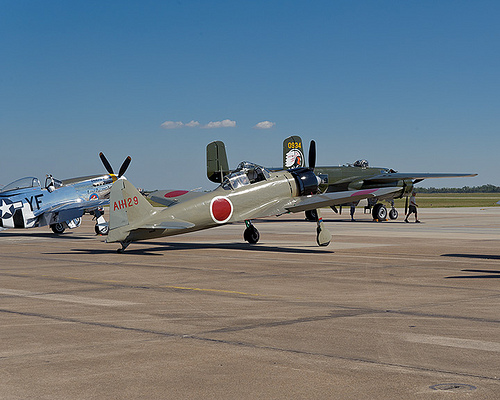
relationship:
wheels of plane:
[369, 182, 436, 222] [286, 129, 448, 214]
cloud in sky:
[154, 117, 199, 134] [3, 2, 498, 169]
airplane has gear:
[104, 134, 403, 254] [315, 220, 332, 247]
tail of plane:
[275, 129, 317, 172] [167, 143, 383, 243]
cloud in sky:
[255, 116, 274, 133] [2, 2, 497, 189]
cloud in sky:
[206, 118, 237, 128] [2, 2, 497, 189]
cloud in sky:
[154, 117, 199, 134] [2, 2, 497, 189]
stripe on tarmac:
[1, 269, 248, 294] [0, 202, 497, 398]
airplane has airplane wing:
[84, 128, 484, 255] [366, 168, 479, 183]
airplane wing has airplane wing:
[285, 188, 406, 208] [146, 185, 211, 205]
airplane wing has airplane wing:
[285, 188, 406, 208] [48, 196, 108, 212]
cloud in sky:
[255, 120, 276, 130] [2, 2, 497, 189]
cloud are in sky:
[154, 117, 199, 134] [2, 2, 497, 189]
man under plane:
[403, 190, 421, 224] [198, 133, 468, 250]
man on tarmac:
[403, 190, 421, 224] [0, 202, 497, 398]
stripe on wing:
[346, 187, 377, 202] [297, 186, 400, 207]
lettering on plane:
[107, 189, 145, 213] [90, 154, 342, 239]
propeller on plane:
[97, 151, 133, 178] [84, 131, 481, 253]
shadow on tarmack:
[66, 241, 332, 261] [68, 291, 410, 366]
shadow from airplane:
[66, 241, 332, 261] [104, 134, 403, 254]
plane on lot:
[1, 148, 137, 232] [7, 196, 494, 397]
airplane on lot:
[104, 134, 403, 254] [7, 196, 494, 397]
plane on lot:
[297, 163, 479, 220] [7, 196, 494, 397]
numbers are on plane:
[283, 139, 305, 149] [93, 158, 402, 268]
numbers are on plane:
[102, 191, 144, 220] [97, 138, 419, 256]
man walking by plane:
[403, 190, 421, 224] [78, 87, 495, 331]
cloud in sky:
[206, 118, 237, 128] [260, 2, 463, 67]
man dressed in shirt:
[402, 188, 424, 223] [407, 194, 419, 209]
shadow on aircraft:
[40, 241, 332, 261] [95, 137, 405, 254]